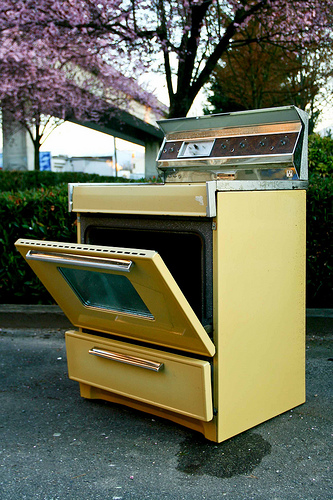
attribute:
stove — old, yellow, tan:
[5, 100, 323, 457]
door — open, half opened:
[8, 232, 223, 360]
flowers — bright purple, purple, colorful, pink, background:
[3, 5, 331, 126]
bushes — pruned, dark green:
[1, 163, 68, 243]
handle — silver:
[24, 247, 140, 279]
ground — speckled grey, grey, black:
[8, 327, 329, 495]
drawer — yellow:
[56, 329, 220, 431]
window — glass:
[54, 258, 160, 327]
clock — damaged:
[173, 137, 223, 158]